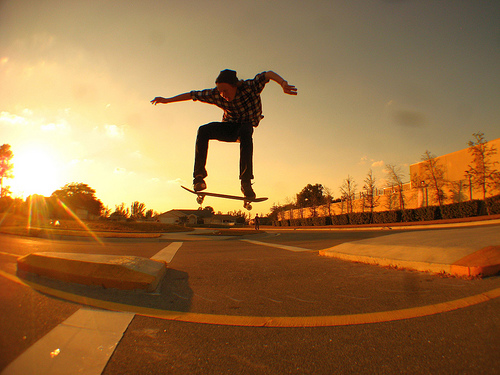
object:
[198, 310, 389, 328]
stripe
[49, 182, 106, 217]
tree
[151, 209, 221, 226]
house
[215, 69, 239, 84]
hat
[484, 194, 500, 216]
shrub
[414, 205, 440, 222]
shrub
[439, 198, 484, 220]
shrub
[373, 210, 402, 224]
shrub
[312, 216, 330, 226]
shrub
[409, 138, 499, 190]
wall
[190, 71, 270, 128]
plaid shirt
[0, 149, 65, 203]
light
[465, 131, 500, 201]
tree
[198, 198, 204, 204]
wheels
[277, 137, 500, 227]
building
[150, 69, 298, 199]
teenager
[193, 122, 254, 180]
blue jeans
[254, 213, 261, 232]
friend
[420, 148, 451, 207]
tree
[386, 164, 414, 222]
tree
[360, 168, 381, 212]
tree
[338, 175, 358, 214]
tree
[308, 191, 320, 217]
tree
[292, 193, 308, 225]
tree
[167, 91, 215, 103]
extended arm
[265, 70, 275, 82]
arm twisted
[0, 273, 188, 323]
stripe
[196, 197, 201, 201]
wheel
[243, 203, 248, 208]
wheel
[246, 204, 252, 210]
wheel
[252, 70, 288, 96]
arm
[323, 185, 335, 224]
tree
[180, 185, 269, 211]
skateboard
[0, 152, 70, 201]
sun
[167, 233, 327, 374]
road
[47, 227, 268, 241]
sidewalk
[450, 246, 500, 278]
red paint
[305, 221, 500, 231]
curb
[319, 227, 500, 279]
panel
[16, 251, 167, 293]
panel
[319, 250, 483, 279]
angles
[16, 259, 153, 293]
angles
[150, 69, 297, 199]
boy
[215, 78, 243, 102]
head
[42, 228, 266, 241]
pavement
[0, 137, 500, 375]
skate park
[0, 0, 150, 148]
sky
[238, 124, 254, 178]
left leg